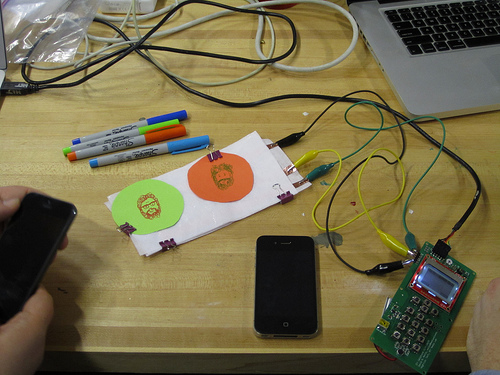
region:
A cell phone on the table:
[243, 222, 334, 349]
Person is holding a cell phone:
[1, 172, 90, 372]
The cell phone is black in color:
[238, 222, 337, 348]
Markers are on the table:
[47, 97, 238, 179]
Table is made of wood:
[3, 4, 499, 368]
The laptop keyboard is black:
[381, 0, 496, 67]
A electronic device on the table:
[352, 228, 492, 372]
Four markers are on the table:
[53, 104, 216, 178]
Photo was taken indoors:
[1, 2, 492, 374]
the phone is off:
[210, 225, 340, 338]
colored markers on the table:
[67, 90, 208, 161]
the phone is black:
[228, 218, 334, 349]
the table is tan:
[202, 71, 380, 278]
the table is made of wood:
[245, 45, 391, 270]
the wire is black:
[434, 120, 481, 250]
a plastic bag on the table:
[8, 0, 100, 78]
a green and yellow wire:
[364, 142, 414, 247]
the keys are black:
[397, 2, 491, 58]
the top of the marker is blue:
[162, 132, 213, 157]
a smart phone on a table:
[245, 230, 320, 341]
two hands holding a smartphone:
[0, 181, 75, 371]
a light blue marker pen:
[85, 130, 207, 170]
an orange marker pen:
[65, 120, 185, 156]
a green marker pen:
[63, 117, 179, 152]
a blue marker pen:
[70, 105, 187, 142]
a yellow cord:
[293, 146, 414, 254]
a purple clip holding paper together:
[201, 141, 221, 161]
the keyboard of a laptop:
[347, 0, 497, 111]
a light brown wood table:
[1, 1, 498, 371]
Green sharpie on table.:
[130, 121, 189, 136]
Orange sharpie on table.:
[136, 122, 182, 141]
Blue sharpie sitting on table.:
[170, 138, 210, 153]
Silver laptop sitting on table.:
[378, 25, 422, 92]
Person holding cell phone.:
[5, 207, 62, 323]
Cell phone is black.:
[22, 198, 89, 273]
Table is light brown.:
[106, 253, 158, 303]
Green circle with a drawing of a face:
[111, 177, 185, 236]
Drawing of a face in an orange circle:
[188, 151, 252, 205]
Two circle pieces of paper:
[110, 150, 253, 233]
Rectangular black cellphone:
[254, 233, 320, 340]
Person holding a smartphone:
[0, 185, 80, 374]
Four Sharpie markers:
[62, 108, 209, 168]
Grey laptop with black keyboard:
[345, 0, 497, 121]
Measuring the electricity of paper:
[266, 87, 483, 282]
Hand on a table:
[465, 272, 497, 373]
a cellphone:
[258, 235, 319, 331]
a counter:
[165, 275, 218, 315]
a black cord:
[336, 248, 358, 270]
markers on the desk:
[57, 110, 211, 157]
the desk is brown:
[127, 284, 191, 331]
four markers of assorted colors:
[46, 103, 209, 176]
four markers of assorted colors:
[56, 105, 220, 167]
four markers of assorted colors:
[60, 108, 215, 175]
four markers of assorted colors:
[57, 105, 219, 175]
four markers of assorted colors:
[58, 103, 215, 175]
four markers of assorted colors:
[58, 105, 206, 177]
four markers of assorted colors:
[50, 103, 205, 172]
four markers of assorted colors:
[49, 103, 218, 176]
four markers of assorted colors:
[63, 102, 215, 170]